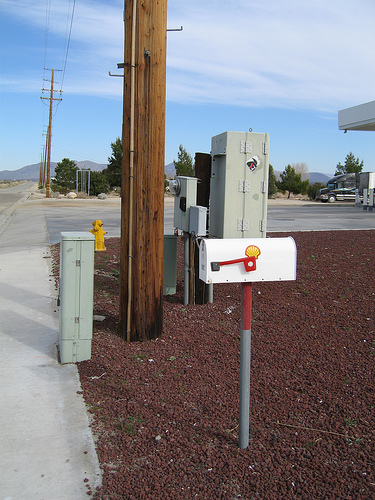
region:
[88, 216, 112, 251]
A yellow fire hydrant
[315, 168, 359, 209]
A black semi truck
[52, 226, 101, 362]
A small green electric box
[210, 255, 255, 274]
A red mailbox flag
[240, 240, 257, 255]
A shell gas logo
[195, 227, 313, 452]
A white/red mailbox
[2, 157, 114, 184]
A very hilled/mountainous terrain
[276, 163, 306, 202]
A small tree in the backround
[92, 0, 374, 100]
A high up large cloud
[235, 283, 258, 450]
A red/silver mailbox pole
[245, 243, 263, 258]
Yellow and red shell symbol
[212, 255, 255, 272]
Red flag attached to mailbox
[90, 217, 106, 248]
Yellow fire hydrant on red gravel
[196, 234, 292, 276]
White metal mailbox with flag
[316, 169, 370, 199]
Large black semi truck in background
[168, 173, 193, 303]
Tall grey metal electrical meter attached to pole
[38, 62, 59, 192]
Tall brown wooden electrical power pole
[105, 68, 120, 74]
Metal stake inserted into pole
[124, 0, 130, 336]
Long tan weather proof lining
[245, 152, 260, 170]
Black and white sticker on side of box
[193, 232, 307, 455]
white mail box with a Shell logo on it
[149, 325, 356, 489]
brown gravel around mail box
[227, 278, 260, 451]
gray and red pole holding mail box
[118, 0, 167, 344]
utility pole in brown gravel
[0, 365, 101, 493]
gray cement sidewalk by brown gravel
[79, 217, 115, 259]
yellow fire hydrant in brown gravel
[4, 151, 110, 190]
mountains in the far distance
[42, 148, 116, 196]
pine trees at the side of the road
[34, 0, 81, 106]
power lines on the side of the road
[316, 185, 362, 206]
black and white car stopped to fill up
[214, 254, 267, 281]
red sign on mailbox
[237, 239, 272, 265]
red and yellow sticker on mailbox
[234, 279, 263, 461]
pole is red and gray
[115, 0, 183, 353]
pole made of wood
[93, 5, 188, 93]
metal pieces hooks sticking out of pole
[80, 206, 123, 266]
the fire hydrant is yellow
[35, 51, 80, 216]
the poles are brown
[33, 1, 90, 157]
electrical wires attached to poles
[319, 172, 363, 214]
car in the background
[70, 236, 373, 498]
rocks on the ground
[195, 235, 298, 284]
a mail box with shell on it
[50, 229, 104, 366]
a phone box on the sidewalk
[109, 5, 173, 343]
a wooden electrical pole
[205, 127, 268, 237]
a utility box by a parking lot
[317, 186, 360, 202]
a car parked in a parking lot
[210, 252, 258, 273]
the red flag on a mail box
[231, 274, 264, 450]
a red and grey mail box pole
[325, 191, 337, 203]
the wheel of a car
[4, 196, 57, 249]
the entrance to parking lot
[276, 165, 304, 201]
a tree by a parking lot